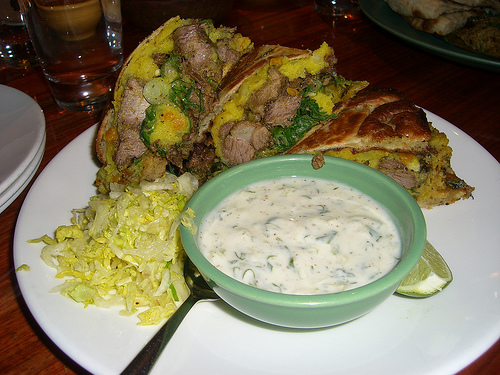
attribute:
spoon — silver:
[98, 292, 202, 374]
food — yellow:
[36, 178, 191, 322]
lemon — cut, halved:
[394, 240, 456, 302]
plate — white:
[14, 87, 489, 374]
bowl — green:
[176, 151, 428, 331]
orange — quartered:
[396, 239, 450, 299]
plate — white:
[42, 299, 353, 373]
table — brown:
[2, 20, 497, 372]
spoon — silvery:
[166, 280, 205, 349]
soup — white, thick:
[198, 172, 400, 294]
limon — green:
[396, 234, 454, 287]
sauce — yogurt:
[191, 167, 404, 295]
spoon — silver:
[114, 261, 221, 373]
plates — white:
[0, 82, 46, 213]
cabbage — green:
[25, 168, 199, 323]